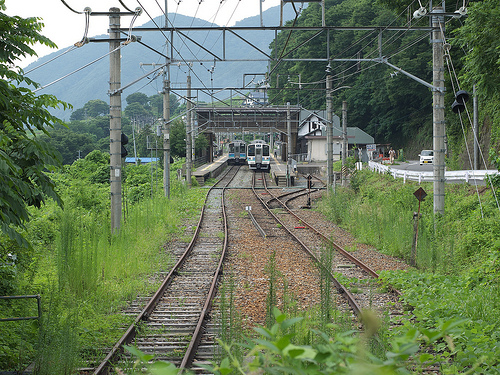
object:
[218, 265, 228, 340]
weeds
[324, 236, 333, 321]
weeds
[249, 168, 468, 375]
train track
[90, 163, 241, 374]
train track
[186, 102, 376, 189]
train station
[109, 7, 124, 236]
pole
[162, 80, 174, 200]
pole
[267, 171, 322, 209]
side track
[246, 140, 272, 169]
train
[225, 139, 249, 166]
train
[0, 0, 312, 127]
mountains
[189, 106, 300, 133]
cover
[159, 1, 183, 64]
wire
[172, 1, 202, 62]
wire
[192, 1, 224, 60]
wire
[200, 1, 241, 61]
wire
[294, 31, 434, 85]
wire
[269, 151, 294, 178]
platform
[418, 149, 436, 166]
car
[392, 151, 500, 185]
street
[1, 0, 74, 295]
tree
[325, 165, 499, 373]
weeds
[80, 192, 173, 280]
grass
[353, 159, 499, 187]
guardrail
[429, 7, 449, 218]
pole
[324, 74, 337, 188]
pole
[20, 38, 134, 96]
wire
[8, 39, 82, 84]
wire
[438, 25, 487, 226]
wire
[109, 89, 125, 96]
bracket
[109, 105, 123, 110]
bracket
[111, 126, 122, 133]
bracket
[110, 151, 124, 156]
bracket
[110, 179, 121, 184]
bracket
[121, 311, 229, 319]
tie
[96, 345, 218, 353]
tie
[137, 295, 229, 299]
tie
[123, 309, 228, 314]
tie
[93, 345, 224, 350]
tie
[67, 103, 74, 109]
leaf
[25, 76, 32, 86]
leaf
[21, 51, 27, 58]
leaf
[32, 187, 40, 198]
leaf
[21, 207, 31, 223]
leaf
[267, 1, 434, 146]
trees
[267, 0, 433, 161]
mountainside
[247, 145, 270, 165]
front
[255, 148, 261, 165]
door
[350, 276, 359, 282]
weeds